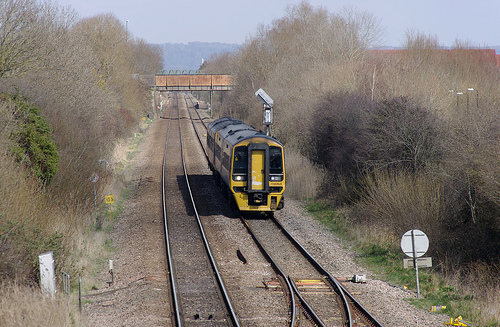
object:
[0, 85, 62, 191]
tree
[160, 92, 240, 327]
track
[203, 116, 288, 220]
train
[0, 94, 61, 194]
trees